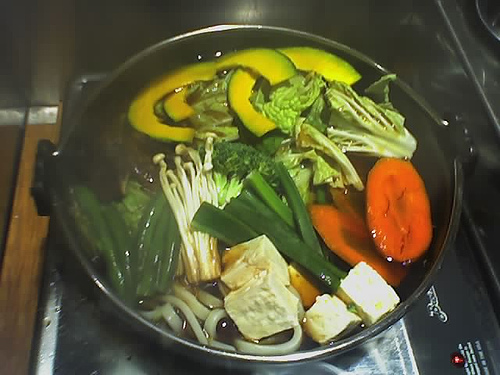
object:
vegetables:
[76, 35, 438, 339]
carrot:
[361, 155, 436, 265]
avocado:
[222, 41, 361, 140]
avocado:
[126, 38, 297, 146]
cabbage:
[108, 168, 154, 232]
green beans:
[128, 189, 170, 294]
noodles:
[147, 280, 307, 359]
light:
[448, 351, 467, 368]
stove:
[16, 58, 500, 374]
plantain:
[278, 262, 329, 309]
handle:
[26, 133, 56, 221]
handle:
[438, 101, 481, 174]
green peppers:
[113, 129, 146, 198]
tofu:
[214, 229, 307, 342]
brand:
[418, 277, 450, 329]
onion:
[287, 165, 312, 202]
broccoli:
[204, 134, 279, 212]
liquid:
[87, 131, 122, 168]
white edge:
[33, 228, 71, 375]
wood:
[0, 100, 61, 371]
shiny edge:
[209, 346, 352, 366]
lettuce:
[267, 72, 421, 191]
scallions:
[264, 170, 319, 261]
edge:
[241, 161, 260, 193]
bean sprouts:
[150, 133, 236, 290]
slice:
[156, 83, 196, 121]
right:
[415, 307, 500, 373]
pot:
[33, 16, 473, 368]